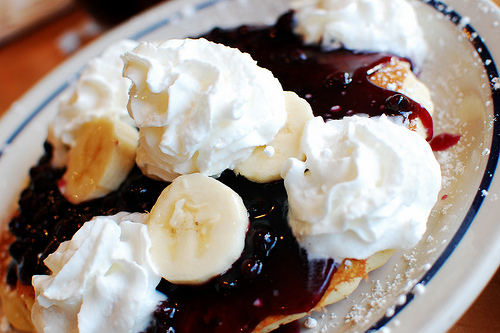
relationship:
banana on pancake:
[138, 176, 259, 284] [0, 30, 423, 331]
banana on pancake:
[208, 88, 320, 179] [0, 30, 423, 331]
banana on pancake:
[52, 117, 139, 197] [0, 30, 423, 331]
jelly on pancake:
[153, 168, 336, 331] [0, 30, 423, 331]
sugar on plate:
[418, 61, 488, 126] [371, 208, 478, 323]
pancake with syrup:
[383, 62, 428, 97] [282, 53, 360, 101]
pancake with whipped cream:
[383, 62, 428, 97] [307, 135, 435, 239]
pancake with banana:
[383, 62, 428, 97] [144, 170, 252, 284]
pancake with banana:
[383, 62, 428, 97] [58, 119, 141, 201]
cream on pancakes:
[280, 113, 441, 253] [0, 26, 433, 331]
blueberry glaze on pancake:
[153, 170, 333, 330] [0, 0, 442, 332]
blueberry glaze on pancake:
[11, 195, 68, 239] [0, 0, 442, 332]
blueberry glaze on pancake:
[322, 70, 366, 108] [0, 0, 442, 332]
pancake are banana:
[0, 30, 423, 331] [42, 77, 326, 293]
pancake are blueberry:
[0, 30, 423, 331] [3, 6, 465, 331]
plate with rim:
[21, 14, 497, 308] [436, 2, 496, 90]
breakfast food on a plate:
[13, 52, 420, 287] [21, 14, 497, 308]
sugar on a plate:
[302, 232, 455, 332] [3, 5, 493, 332]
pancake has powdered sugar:
[0, 30, 423, 331] [382, 62, 422, 98]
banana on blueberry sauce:
[138, 176, 259, 284] [216, 182, 329, 322]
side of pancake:
[256, 255, 363, 330] [0, 30, 423, 331]